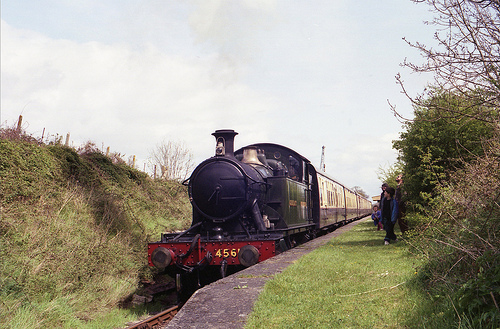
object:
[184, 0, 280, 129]
smoke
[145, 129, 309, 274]
engine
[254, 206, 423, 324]
field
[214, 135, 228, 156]
bell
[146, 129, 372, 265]
train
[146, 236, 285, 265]
cow catcher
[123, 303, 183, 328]
train track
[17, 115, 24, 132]
fence post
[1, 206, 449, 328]
grass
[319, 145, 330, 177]
crane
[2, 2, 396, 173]
background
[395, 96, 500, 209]
trees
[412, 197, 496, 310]
shrubs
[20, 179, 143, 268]
weeds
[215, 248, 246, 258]
numbers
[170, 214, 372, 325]
path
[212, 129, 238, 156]
smoke stack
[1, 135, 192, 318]
hillside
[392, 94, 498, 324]
bushes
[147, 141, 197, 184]
tree branches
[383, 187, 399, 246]
person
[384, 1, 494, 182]
tree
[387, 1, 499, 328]
sideview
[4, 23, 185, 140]
clouds